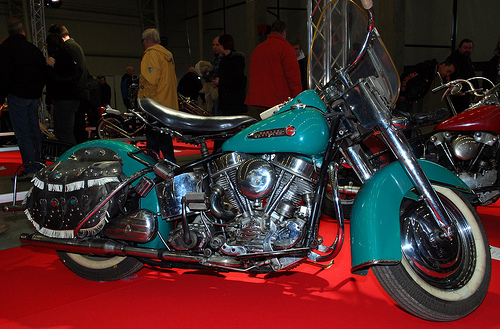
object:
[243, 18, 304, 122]
man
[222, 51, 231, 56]
neck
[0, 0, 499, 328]
display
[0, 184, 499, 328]
carpet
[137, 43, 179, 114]
jacket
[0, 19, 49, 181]
men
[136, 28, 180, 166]
man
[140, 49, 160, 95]
arm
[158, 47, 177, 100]
back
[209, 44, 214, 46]
eyes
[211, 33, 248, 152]
man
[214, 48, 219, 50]
nose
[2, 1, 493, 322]
motorcycle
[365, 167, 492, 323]
front tire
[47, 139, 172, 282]
back tire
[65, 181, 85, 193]
fringe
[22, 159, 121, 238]
saddle bag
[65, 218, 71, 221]
studs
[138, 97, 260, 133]
motorcycle seat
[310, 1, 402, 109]
windshield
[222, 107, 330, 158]
gas tank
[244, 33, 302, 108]
jacket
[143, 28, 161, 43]
hair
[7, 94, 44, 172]
jean pants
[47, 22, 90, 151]
woman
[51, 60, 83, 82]
purse